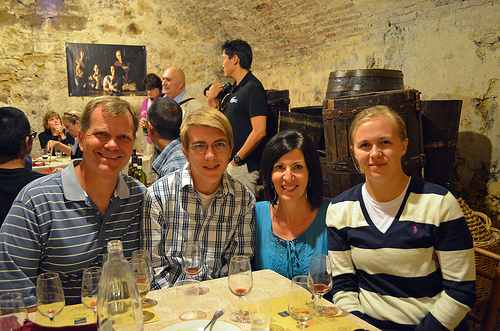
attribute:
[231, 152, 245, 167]
watch — black, wrist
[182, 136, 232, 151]
glasses — eye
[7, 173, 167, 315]
shirt — striped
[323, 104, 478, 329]
girl — white, striped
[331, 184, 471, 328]
shirt — navy blue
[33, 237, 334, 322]
glasses — wine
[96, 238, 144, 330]
bottle — clear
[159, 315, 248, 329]
plate — empty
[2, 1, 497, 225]
wall — brick, old, aged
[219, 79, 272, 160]
shirt — black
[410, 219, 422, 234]
logo — pink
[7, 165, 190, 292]
shirt — polo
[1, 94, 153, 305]
man — smiling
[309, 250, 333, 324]
glass — wine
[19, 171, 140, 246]
shirt — striped, white, blue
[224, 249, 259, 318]
wine glass — empty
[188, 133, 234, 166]
glasses — eye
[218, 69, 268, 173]
shirt — black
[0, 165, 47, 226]
shirt — black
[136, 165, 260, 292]
shirt — plaid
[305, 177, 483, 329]
shirt — tee, white, plain 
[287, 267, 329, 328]
glass — empty, wine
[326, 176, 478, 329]
shirt — striped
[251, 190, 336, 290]
sweater — blue, turquoise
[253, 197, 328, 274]
shirt — blue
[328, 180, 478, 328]
sweater — striped 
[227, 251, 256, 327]
wine glass — empty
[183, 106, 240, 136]
hair — blonde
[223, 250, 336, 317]
glass — empty